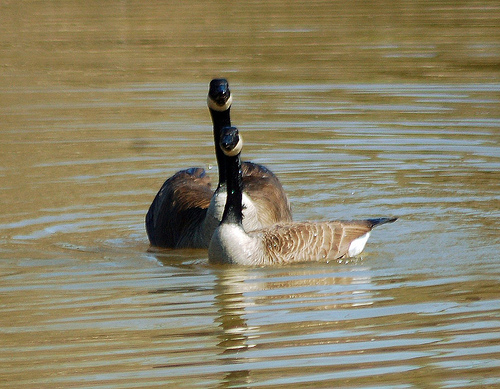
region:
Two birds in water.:
[62, 39, 442, 324]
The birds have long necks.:
[103, 48, 440, 312]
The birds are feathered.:
[103, 55, 431, 304]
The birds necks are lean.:
[116, 49, 426, 304]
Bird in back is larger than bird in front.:
[111, 55, 423, 292]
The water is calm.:
[2, 1, 493, 386]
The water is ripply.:
[1, 0, 496, 385]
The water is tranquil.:
[0, 0, 495, 380]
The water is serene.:
[0, 0, 495, 385]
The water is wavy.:
[0, 1, 498, 386]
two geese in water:
[136, 65, 397, 266]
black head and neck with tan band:
[202, 75, 242, 221]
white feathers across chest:
[207, 220, 257, 265]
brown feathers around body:
[255, 206, 370, 261]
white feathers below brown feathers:
[335, 211, 371, 256]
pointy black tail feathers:
[362, 210, 397, 235]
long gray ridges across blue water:
[11, 250, 481, 371]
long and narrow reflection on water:
[201, 265, 257, 380]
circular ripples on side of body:
[50, 187, 200, 277]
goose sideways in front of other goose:
[143, 71, 398, 278]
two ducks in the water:
[102, 38, 412, 303]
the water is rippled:
[129, 257, 454, 381]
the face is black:
[205, 122, 240, 149]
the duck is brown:
[236, 200, 369, 293]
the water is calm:
[207, 40, 455, 315]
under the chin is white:
[203, 95, 230, 116]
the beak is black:
[215, 135, 233, 150]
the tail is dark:
[346, 200, 406, 247]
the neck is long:
[192, 157, 267, 229]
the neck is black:
[201, 158, 264, 225]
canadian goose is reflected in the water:
[113, 253, 312, 388]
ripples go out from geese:
[18, 191, 493, 387]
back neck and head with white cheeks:
[196, 69, 253, 234]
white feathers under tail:
[338, 219, 372, 263]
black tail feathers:
[361, 208, 402, 233]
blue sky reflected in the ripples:
[287, 81, 490, 246]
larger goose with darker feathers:
[146, 74, 289, 251]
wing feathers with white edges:
[208, 122, 402, 268]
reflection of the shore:
[8, 3, 498, 95]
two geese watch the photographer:
[145, 54, 406, 264]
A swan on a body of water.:
[202, 110, 402, 265]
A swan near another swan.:
[140, 71, 291, 267]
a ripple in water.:
[39, 283, 499, 306]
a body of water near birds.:
[0, 0, 490, 69]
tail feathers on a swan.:
[340, 193, 411, 278]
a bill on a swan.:
[215, 85, 230, 107]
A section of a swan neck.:
[207, 168, 232, 200]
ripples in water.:
[1, 194, 137, 269]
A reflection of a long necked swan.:
[199, 270, 283, 380]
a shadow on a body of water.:
[126, 126, 158, 157]